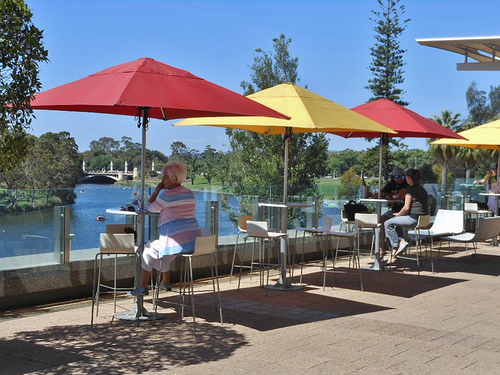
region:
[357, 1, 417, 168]
tall green tree in green field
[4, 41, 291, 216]
red dining table umbrella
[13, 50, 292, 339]
woman sitting at outdoor dining table on cell phone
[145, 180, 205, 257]
pink and blue sweater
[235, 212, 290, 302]
white short back chair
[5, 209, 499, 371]
tan brick paved walkway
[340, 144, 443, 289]
two people sitting at outdoor dining table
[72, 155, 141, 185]
bridge over body of water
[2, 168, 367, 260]
large body of water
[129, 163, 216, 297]
this is a lady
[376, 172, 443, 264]
this is a lady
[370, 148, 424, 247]
this is a lady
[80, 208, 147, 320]
this is a chair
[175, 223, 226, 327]
this is a chair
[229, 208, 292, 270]
this is a chair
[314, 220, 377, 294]
this is a chair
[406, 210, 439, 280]
this is a chair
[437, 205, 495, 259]
this is a chair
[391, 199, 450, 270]
this is a chair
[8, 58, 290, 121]
An open red umbrella.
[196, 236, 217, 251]
Part of a chair.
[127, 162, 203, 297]
A woman sitting down.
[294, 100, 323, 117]
Part of a yellow umbrella.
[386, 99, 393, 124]
Part of a red umbrella.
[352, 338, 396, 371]
Part of the ground.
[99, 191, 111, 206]
Part of the water.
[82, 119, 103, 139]
Part of the sky.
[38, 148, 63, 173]
Part of a green tree.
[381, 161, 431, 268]
A couple is at a table.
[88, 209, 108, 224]
Boats are in the water.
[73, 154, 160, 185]
There is a bridge over the water.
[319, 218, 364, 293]
There are white chairs at the tables.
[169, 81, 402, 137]
There are umbrellas over the tables.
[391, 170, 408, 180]
The man is wearing sunglasses.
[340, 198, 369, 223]
A black bag is in a chair.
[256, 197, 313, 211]
The tables are white.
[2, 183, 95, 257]
There is a glass covering in front of the tables and deck.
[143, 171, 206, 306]
Woman sitting at a table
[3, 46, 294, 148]
Red umbrella over the table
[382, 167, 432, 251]
Lady wearing blue jeans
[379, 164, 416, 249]
Man sitting at the table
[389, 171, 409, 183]
Glasses on the man's face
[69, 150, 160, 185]
Bridge in the background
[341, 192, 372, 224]
Bag on the chair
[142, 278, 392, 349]
Shadow on the ground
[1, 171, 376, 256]
Body of water in the background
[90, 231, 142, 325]
white chair with silver metal legs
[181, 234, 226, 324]
white chair with silver metal legs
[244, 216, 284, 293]
white chair with silver metal legs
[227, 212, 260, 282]
white chair with silver metal legs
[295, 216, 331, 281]
white chair with silver metal legs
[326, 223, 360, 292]
white chair with silver metal legs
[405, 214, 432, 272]
white chair with silver metal legs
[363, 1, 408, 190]
tall thin tree with green leaves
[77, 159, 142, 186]
white bridge crossing over the blue water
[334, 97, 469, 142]
large red open umbrella on a pole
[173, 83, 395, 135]
large yellow open umbrella on a pole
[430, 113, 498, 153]
large yellow open umbrella on a pole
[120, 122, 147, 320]
tall silver pole with round base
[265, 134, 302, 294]
tall silver pole with round base